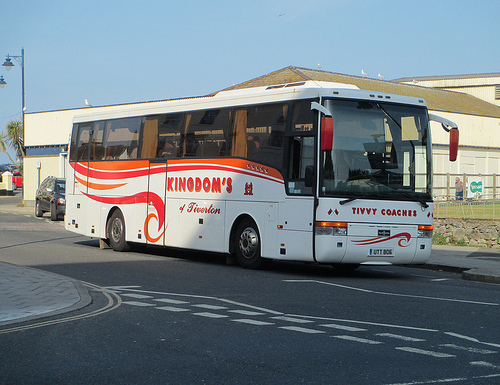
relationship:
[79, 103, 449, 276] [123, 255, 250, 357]
bus on road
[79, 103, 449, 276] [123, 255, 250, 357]
bus in road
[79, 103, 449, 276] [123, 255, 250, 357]
bus near road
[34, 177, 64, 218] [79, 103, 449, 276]
car behind bus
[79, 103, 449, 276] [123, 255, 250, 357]
bus traveling on road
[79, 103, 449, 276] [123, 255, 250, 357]
bus on top of road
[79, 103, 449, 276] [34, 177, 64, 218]
bus near car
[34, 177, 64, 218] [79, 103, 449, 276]
car near bus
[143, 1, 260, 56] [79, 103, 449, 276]
sky above bus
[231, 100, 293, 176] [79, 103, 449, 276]
window on bus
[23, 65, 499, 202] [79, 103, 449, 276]
building behind bus